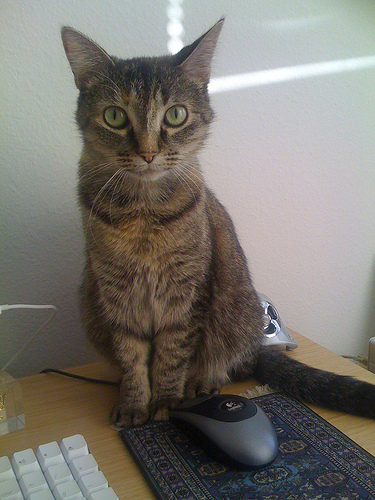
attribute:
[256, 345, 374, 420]
tail — gray, dark, black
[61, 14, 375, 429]
cat — alert, sitting, brown, gray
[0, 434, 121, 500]
keyboard — white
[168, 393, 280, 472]
mouse — black, gray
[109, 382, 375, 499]
mousepad — colorful, blue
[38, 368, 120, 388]
cord — black, dark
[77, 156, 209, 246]
whiskers — long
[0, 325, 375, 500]
desk — brown, wooden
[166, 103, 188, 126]
eye — green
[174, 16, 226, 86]
ear — pointed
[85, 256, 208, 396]
legs — brown, black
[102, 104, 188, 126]
eyes — round, yellow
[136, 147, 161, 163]
nose — pink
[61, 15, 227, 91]
ears — brown